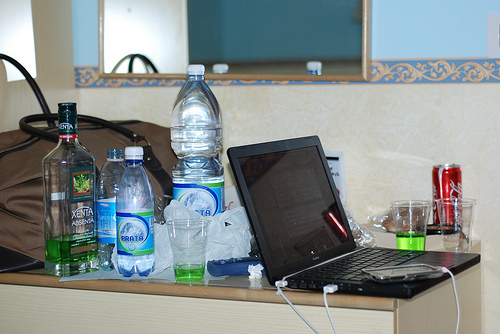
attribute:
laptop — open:
[217, 134, 489, 301]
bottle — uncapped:
[114, 125, 167, 282]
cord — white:
[273, 278, 315, 332]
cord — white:
[318, 281, 340, 332]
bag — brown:
[2, 94, 192, 272]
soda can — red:
[428, 161, 466, 196]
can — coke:
[421, 151, 463, 226]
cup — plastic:
[167, 211, 215, 287]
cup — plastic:
[389, 193, 433, 250]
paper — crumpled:
[247, 259, 269, 290]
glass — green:
[158, 209, 227, 289]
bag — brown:
[14, 103, 216, 301]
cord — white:
[320, 284, 344, 332]